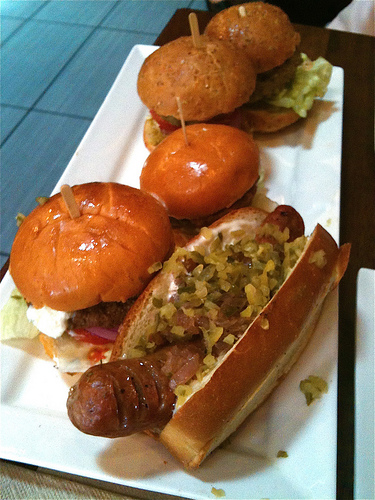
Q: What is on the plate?
A: Hot dog.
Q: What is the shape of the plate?
A: Rectangle.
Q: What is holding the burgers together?
A: Toothpick.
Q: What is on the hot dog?
A: Relish.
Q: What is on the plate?
A: Food.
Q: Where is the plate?
A: On a table.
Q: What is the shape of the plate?
A: Rectangle.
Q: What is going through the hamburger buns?
A: Wooden sticks.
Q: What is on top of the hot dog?
A: Relish.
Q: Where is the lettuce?
A: On the hamburgers.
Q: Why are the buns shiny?
A: They are greasy.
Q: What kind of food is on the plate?
A: Hamburgers and hotdog.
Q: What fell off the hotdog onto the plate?
A: Relish.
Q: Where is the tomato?
A: In the hamburgers.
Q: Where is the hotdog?
A: On a white tray.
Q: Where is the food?
A: On a tray.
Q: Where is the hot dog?
A: Next to the hamburger.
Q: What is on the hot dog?
A: Pickles.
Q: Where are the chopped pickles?
A: On the hot dog.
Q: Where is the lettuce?
A: In the hamburger.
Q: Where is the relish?
A: On the hot dog.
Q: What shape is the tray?
A: Rectangular.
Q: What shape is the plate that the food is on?
A: Rectangulare.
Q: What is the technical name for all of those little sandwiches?
A: Sliders.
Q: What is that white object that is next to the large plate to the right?
A: A smalled sized plate.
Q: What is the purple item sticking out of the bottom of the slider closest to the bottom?
A: Slice of purple onion.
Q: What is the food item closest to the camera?
A: Sausage.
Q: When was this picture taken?
A: Daytime.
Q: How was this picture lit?
A: Natural light.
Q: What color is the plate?
A: White.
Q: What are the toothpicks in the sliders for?
A: To hold them together.